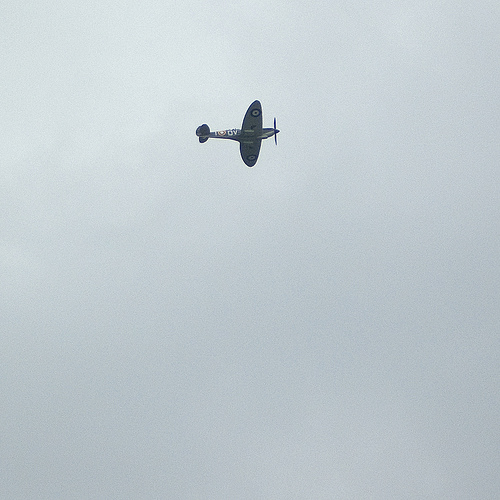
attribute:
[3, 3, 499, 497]
sky — cloudy, dark, clear